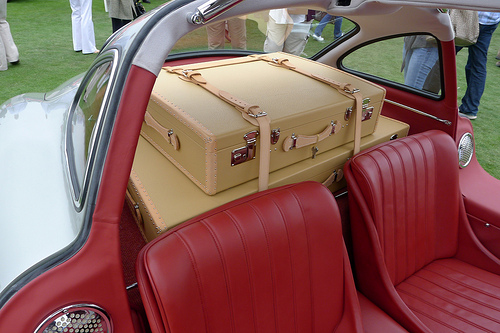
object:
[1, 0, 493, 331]
car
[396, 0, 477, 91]
people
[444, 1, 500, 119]
people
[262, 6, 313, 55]
people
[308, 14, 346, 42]
people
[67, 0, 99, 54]
people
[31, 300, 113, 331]
speaker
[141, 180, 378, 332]
seat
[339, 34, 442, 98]
window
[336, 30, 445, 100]
edge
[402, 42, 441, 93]
leg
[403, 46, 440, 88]
jeans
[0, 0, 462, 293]
trunk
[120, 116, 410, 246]
suitcases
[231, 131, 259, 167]
latches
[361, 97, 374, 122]
latches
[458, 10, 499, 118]
person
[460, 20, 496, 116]
pants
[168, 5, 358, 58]
window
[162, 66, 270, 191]
luggage strap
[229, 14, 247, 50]
partial legs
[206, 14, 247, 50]
khaki pants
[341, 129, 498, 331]
car seat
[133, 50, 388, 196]
case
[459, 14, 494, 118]
leg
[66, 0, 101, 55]
person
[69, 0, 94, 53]
pants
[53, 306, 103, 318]
top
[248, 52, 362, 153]
strap